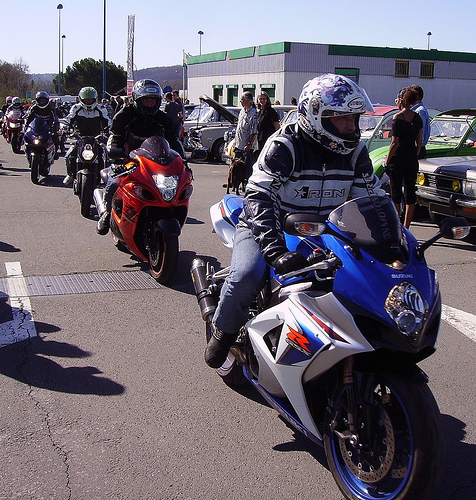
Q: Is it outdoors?
A: Yes, it is outdoors.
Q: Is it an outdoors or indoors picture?
A: It is outdoors.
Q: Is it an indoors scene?
A: No, it is outdoors.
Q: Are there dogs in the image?
A: Yes, there is a dog.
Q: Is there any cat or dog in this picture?
A: Yes, there is a dog.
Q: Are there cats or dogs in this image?
A: Yes, there is a dog.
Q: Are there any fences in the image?
A: No, there are no fences.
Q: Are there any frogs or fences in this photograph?
A: No, there are no fences or frogs.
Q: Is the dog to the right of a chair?
A: No, the dog is to the right of a person.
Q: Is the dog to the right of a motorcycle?
A: Yes, the dog is to the right of a motorcycle.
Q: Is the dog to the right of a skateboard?
A: No, the dog is to the right of a motorcycle.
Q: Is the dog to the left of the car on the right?
A: Yes, the dog is to the left of the car.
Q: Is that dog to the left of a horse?
A: No, the dog is to the left of the car.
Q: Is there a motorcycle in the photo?
A: Yes, there is a motorcycle.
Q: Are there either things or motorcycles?
A: Yes, there is a motorcycle.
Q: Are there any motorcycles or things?
A: Yes, there is a motorcycle.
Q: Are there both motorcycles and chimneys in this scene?
A: No, there is a motorcycle but no chimneys.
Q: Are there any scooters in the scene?
A: No, there are no scooters.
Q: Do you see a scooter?
A: No, there are no scooters.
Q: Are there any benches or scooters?
A: No, there are no scooters or benches.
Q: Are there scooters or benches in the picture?
A: No, there are no scooters or benches.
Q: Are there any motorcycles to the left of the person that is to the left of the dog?
A: Yes, there is a motorcycle to the left of the person.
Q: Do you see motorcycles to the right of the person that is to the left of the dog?
A: No, the motorcycle is to the left of the person.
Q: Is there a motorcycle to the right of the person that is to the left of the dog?
A: No, the motorcycle is to the left of the person.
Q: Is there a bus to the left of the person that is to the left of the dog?
A: No, there is a motorcycle to the left of the person.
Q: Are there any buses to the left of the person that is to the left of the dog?
A: No, there is a motorcycle to the left of the person.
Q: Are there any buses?
A: No, there are no buses.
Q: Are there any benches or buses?
A: No, there are no buses or benches.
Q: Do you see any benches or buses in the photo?
A: No, there are no buses or benches.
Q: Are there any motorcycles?
A: Yes, there is a motorcycle.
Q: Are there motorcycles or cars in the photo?
A: Yes, there is a motorcycle.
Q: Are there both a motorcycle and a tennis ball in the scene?
A: No, there is a motorcycle but no tennis balls.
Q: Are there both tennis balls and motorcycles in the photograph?
A: No, there is a motorcycle but no tennis balls.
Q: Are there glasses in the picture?
A: No, there are no glasses.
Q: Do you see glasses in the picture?
A: No, there are no glasses.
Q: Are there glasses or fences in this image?
A: No, there are no glasses or fences.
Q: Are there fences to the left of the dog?
A: No, there is a motorcycle to the left of the dog.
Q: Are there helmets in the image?
A: Yes, there is a helmet.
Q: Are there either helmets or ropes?
A: Yes, there is a helmet.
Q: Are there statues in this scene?
A: No, there are no statues.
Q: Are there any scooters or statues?
A: No, there are no statues or scooters.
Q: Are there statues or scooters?
A: No, there are no statues or scooters.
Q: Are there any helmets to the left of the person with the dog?
A: Yes, there is a helmet to the left of the person.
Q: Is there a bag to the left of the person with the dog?
A: No, there is a helmet to the left of the person.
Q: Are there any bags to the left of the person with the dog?
A: No, there is a helmet to the left of the person.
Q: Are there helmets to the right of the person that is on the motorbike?
A: Yes, there is a helmet to the right of the person.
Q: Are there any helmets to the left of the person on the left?
A: No, the helmet is to the right of the person.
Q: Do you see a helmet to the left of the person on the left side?
A: No, the helmet is to the right of the person.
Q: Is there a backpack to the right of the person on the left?
A: No, there is a helmet to the right of the person.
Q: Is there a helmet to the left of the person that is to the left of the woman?
A: Yes, there is a helmet to the left of the person.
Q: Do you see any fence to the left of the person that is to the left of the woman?
A: No, there is a helmet to the left of the person.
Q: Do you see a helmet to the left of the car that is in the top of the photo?
A: Yes, there is a helmet to the left of the car.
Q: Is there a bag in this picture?
A: No, there are no bags.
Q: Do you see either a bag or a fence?
A: No, there are no bags or fences.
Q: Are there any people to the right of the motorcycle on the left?
A: Yes, there is a person to the right of the motorbike.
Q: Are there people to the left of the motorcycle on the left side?
A: No, the person is to the right of the motorbike.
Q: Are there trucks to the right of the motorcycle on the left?
A: No, there is a person to the right of the motorcycle.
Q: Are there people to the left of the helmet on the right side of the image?
A: Yes, there is a person to the left of the helmet.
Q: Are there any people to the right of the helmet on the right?
A: No, the person is to the left of the helmet.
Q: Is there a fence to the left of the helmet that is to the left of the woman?
A: No, there is a person to the left of the helmet.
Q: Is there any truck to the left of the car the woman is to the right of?
A: No, there is a person to the left of the car.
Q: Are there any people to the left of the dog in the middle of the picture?
A: Yes, there is a person to the left of the dog.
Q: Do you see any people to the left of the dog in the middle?
A: Yes, there is a person to the left of the dog.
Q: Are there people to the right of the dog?
A: No, the person is to the left of the dog.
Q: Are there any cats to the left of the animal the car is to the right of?
A: No, there is a person to the left of the dog.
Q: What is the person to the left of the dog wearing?
A: The person is wearing a helmet.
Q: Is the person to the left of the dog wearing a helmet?
A: Yes, the person is wearing a helmet.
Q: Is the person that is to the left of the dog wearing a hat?
A: No, the person is wearing a helmet.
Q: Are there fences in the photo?
A: No, there are no fences.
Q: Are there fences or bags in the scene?
A: No, there are no fences or bags.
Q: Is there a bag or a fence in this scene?
A: No, there are no fences or bags.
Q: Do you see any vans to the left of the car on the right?
A: No, there is a person to the left of the car.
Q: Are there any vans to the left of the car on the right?
A: No, there is a person to the left of the car.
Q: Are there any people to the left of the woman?
A: Yes, there is a person to the left of the woman.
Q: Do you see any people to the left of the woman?
A: Yes, there is a person to the left of the woman.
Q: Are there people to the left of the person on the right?
A: Yes, there is a person to the left of the woman.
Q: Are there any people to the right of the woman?
A: No, the person is to the left of the woman.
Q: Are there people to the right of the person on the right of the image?
A: No, the person is to the left of the woman.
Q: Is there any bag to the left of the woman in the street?
A: No, there is a person to the left of the woman.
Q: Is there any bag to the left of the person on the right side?
A: No, there is a person to the left of the woman.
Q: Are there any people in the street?
A: Yes, there is a person in the street.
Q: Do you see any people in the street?
A: Yes, there is a person in the street.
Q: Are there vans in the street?
A: No, there is a person in the street.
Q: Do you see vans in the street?
A: No, there is a person in the street.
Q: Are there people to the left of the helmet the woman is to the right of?
A: Yes, there is a person to the left of the helmet.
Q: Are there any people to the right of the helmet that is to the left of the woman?
A: No, the person is to the left of the helmet.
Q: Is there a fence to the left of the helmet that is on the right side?
A: No, there is a person to the left of the helmet.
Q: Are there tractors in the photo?
A: No, there are no tractors.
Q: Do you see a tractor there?
A: No, there are no tractors.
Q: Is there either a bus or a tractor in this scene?
A: No, there are no tractors or buses.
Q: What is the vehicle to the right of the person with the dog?
A: The vehicle is a car.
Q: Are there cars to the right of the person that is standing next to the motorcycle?
A: Yes, there is a car to the right of the person.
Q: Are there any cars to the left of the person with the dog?
A: No, the car is to the right of the person.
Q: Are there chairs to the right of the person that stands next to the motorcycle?
A: No, there is a car to the right of the person.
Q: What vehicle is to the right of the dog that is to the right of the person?
A: The vehicle is a car.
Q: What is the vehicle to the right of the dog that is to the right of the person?
A: The vehicle is a car.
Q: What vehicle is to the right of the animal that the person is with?
A: The vehicle is a car.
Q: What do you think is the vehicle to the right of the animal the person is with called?
A: The vehicle is a car.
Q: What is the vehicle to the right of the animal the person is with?
A: The vehicle is a car.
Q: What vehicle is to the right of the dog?
A: The vehicle is a car.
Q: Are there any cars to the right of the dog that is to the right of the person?
A: Yes, there is a car to the right of the dog.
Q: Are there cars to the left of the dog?
A: No, the car is to the right of the dog.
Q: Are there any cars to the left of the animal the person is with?
A: No, the car is to the right of the dog.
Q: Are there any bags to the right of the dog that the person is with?
A: No, there is a car to the right of the dog.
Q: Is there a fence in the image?
A: No, there are no fences.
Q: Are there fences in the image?
A: No, there are no fences.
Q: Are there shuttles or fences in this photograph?
A: No, there are no fences or shuttles.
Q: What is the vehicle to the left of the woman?
A: The vehicle is a car.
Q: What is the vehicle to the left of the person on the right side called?
A: The vehicle is a car.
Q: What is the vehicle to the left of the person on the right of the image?
A: The vehicle is a car.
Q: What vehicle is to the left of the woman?
A: The vehicle is a car.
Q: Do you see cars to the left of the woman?
A: Yes, there is a car to the left of the woman.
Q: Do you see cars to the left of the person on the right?
A: Yes, there is a car to the left of the woman.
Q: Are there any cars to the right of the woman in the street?
A: No, the car is to the left of the woman.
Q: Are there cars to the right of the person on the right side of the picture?
A: No, the car is to the left of the woman.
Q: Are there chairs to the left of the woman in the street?
A: No, there is a car to the left of the woman.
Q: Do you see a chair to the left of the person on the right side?
A: No, there is a car to the left of the woman.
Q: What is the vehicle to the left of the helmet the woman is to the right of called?
A: The vehicle is a car.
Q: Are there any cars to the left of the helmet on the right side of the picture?
A: Yes, there is a car to the left of the helmet.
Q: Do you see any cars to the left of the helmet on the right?
A: Yes, there is a car to the left of the helmet.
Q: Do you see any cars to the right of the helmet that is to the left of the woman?
A: No, the car is to the left of the helmet.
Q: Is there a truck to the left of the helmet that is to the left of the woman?
A: No, there is a car to the left of the helmet.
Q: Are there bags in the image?
A: No, there are no bags.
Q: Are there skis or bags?
A: No, there are no bags or skis.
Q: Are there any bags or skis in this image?
A: No, there are no bags or skis.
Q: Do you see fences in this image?
A: No, there are no fences.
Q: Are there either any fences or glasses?
A: No, there are no fences or glasses.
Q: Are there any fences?
A: No, there are no fences.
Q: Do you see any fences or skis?
A: No, there are no fences or skis.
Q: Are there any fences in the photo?
A: No, there are no fences.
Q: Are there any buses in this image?
A: No, there are no buses.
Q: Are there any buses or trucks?
A: No, there are no buses or trucks.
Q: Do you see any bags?
A: No, there are no bags.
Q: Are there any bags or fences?
A: No, there are no bags or fences.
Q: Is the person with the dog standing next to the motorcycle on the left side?
A: Yes, the person is standing next to the motorbike.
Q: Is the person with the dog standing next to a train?
A: No, the person is standing next to the motorbike.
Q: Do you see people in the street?
A: Yes, there is a person in the street.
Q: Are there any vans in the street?
A: No, there is a person in the street.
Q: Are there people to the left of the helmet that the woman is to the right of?
A: Yes, there is a person to the left of the helmet.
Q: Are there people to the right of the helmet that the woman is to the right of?
A: No, the person is to the left of the helmet.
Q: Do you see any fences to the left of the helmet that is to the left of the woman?
A: No, there is a person to the left of the helmet.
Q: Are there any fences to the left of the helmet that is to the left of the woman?
A: No, there is a person to the left of the helmet.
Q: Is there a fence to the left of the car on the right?
A: No, there is a person to the left of the car.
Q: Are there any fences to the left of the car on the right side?
A: No, there is a person to the left of the car.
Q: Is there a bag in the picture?
A: No, there are no bags.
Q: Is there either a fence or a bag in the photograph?
A: No, there are no bags or fences.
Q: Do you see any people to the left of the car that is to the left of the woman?
A: Yes, there is a person to the left of the car.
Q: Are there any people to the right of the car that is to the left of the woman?
A: No, the person is to the left of the car.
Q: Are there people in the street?
A: Yes, there is a person in the street.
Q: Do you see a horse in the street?
A: No, there is a person in the street.